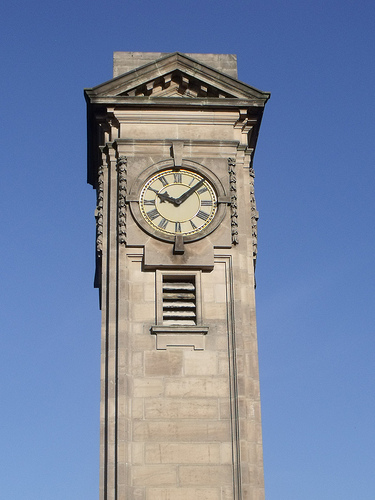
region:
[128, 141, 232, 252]
A clock face has four keystones at the quarter hour marks.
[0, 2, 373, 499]
The sky is blue.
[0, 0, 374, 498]
No clouds are in the sky.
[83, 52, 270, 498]
The building is made of stone.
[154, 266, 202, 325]
A rectangle has horizontal slats in it.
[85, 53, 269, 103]
Dark gray is on the edging.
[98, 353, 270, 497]
Stones have horizontal and vertical lines.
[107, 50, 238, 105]
Two triangles are over a roof.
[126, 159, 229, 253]
A clock reads ten eight o'clock.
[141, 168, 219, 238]
The clock face has Roman numerals.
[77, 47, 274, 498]
tall grey concrete clock tower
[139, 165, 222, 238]
roman numerals around a clock face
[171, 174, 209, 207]
black minute hand on a clock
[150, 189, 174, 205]
back hour hand on a clock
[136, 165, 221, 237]
time is 10:07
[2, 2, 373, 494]
blue sky behind a clock tower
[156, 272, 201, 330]
slats in the side of a stone tower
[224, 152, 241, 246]
carved stone decoration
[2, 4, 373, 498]
sky is blue and cloudless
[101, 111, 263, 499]
brickwork on a tall tower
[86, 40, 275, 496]
a large clock tower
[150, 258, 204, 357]
the shutters of a small window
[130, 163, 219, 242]
a large clock on the wall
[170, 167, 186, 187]
the roman numeral for twelve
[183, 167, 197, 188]
the roman numeral for one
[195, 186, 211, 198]
the roman numeral for two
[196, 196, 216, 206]
the roman numeral for three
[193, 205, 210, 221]
the roman numeral for four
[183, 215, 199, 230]
the roman numeral for five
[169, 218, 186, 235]
the roman numeral for six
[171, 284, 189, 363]
There are concrete vents here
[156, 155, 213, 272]
There is a clock that is visible here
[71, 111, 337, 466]
This photo features a concrete tower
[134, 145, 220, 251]
clock inside of gray tower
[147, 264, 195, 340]
vent at the top of clock tower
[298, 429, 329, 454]
sky is vibrant blue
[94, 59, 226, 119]
decoration at top of clock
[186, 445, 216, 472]
gray and tan bricks on tower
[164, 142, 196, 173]
piece of ornament on clock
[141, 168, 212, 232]
clock says its 10:07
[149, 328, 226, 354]
shelf under vent in tower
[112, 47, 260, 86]
bricks at top of tower